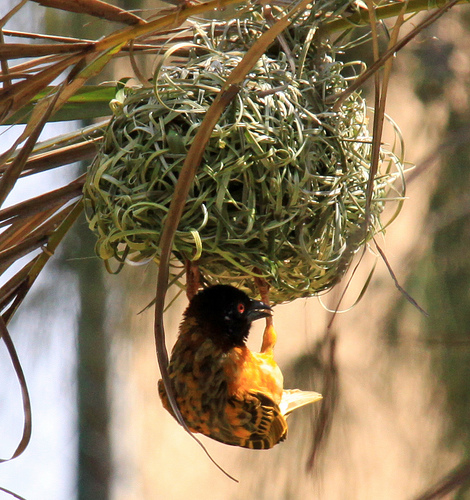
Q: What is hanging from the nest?
A: A Bird.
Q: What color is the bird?
A: Yellow and black.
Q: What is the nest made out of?
A: Grass.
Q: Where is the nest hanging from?
A: Branches.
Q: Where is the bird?
A: Underneath the nest.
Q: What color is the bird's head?
A: Black.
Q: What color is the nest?
A: The nest is green.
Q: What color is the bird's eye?
A: Red.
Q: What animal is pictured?
A: A bird.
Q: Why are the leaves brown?
A: They are dried out.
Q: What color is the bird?
A: Black and yellow.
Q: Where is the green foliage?
A: Just above the bird.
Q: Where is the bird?
A: Hanging from a tree.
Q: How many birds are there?
A: 1.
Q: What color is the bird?
A: Black and yellow.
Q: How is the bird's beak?
A: Open.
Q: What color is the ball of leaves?
A: Green.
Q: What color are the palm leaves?
A: Brown.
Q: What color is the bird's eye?
A: Red.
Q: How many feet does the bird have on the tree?
A: 2.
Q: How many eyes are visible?
A: 1.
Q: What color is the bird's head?
A: Black.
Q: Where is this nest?
A: A tree.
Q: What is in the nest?
A: A bird.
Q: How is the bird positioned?
A: He is hanging from the nest.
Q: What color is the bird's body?
A: Yellow.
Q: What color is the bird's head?
A: Black.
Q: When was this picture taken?
A: In the daytime.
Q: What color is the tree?
A: Green.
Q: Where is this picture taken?
A: In a tree.